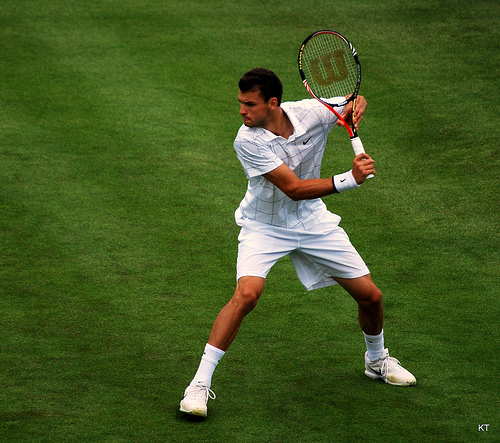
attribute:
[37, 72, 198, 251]
court — green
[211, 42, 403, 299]
man — playing, bending, focused, swinging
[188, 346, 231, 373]
socks — white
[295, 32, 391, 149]
racket — red, wilson, black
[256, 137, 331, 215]
shirt — white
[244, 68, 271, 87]
hair — brown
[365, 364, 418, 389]
shoes — white, nike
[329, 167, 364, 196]
wrist band — white